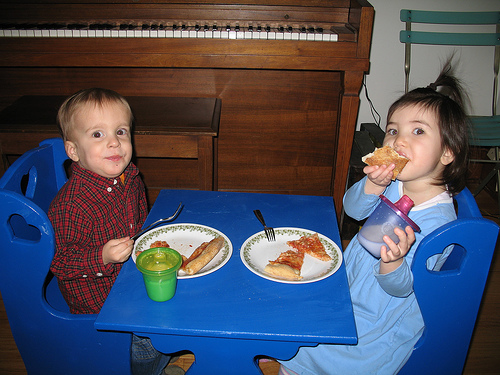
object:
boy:
[47, 84, 197, 374]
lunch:
[131, 220, 234, 277]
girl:
[253, 50, 476, 374]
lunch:
[241, 225, 344, 285]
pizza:
[261, 247, 306, 280]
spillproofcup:
[135, 244, 183, 303]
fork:
[251, 208, 279, 242]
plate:
[237, 226, 346, 285]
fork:
[128, 204, 187, 242]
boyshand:
[98, 234, 135, 266]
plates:
[129, 220, 234, 280]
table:
[93, 186, 360, 346]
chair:
[0, 137, 134, 374]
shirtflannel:
[47, 162, 151, 317]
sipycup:
[355, 192, 422, 262]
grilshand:
[377, 225, 417, 264]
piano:
[4, 0, 377, 236]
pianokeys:
[327, 28, 339, 43]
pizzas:
[287, 232, 332, 261]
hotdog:
[182, 236, 226, 274]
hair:
[55, 87, 134, 141]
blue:
[277, 178, 460, 374]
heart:
[425, 244, 466, 275]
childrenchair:
[397, 182, 500, 374]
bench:
[0, 123, 218, 213]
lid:
[376, 193, 423, 235]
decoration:
[249, 235, 259, 246]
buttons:
[94, 272, 107, 277]